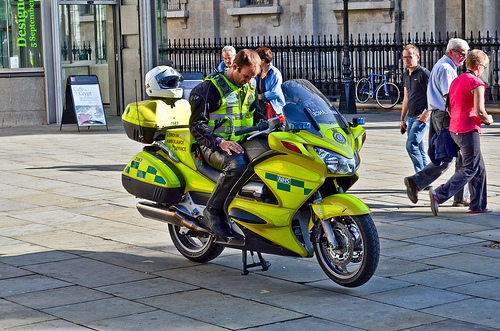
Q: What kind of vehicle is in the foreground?
A: Motorcycle.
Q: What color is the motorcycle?
A: Yellow, green and black.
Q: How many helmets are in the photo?
A: One.